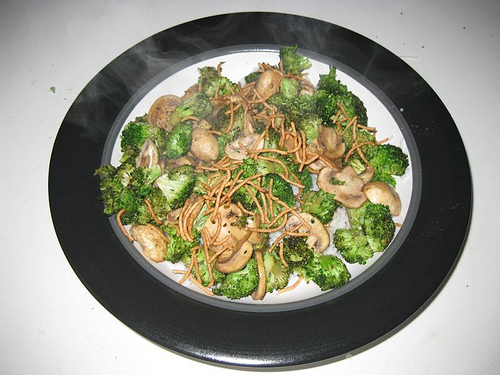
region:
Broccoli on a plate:
[97, 46, 409, 299]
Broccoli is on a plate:
[92, 44, 410, 307]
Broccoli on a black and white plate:
[93, 39, 411, 306]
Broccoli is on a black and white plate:
[92, 42, 412, 308]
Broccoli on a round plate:
[92, 40, 413, 305]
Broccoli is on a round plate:
[92, 40, 413, 309]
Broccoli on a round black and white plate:
[87, 34, 407, 309]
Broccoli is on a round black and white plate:
[89, 40, 414, 306]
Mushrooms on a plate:
[82, 40, 417, 302]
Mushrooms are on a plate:
[82, 45, 409, 296]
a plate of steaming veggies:
[113, 53, 400, 295]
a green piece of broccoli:
[311, 256, 347, 288]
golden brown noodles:
[181, 248, 216, 290]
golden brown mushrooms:
[287, 215, 330, 245]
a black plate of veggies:
[47, 8, 476, 366]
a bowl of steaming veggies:
[41, 9, 473, 363]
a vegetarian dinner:
[45, 14, 468, 353]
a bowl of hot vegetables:
[46, 4, 471, 357]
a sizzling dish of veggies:
[123, 74, 389, 281]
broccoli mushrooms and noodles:
[108, 46, 412, 304]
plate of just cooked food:
[16, 6, 489, 371]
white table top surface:
[421, 317, 496, 364]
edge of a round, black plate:
[40, 117, 90, 287]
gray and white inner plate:
[265, 291, 325, 311]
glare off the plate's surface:
[175, 330, 300, 370]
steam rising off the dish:
[115, 35, 180, 81]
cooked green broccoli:
[305, 255, 345, 285]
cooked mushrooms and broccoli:
[316, 162, 396, 252]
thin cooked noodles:
[200, 155, 235, 205]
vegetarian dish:
[95, 22, 432, 319]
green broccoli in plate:
[136, 79, 409, 306]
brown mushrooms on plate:
[115, 102, 405, 267]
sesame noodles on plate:
[131, 84, 343, 261]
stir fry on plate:
[140, 71, 380, 291]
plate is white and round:
[122, 88, 378, 290]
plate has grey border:
[137, 74, 368, 289]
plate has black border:
[4, 49, 495, 299]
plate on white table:
[77, 34, 427, 343]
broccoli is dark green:
[135, 93, 379, 309]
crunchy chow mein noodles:
[154, 96, 329, 251]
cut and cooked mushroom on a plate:
[363, 175, 408, 216]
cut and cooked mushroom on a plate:
[284, 208, 333, 250]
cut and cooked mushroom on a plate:
[316, 160, 368, 207]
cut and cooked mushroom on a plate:
[129, 220, 166, 262]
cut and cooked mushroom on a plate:
[209, 238, 254, 273]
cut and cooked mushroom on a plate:
[247, 245, 267, 303]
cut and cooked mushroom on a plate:
[187, 123, 219, 163]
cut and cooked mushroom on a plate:
[223, 131, 265, 162]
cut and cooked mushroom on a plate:
[250, 65, 280, 102]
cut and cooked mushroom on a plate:
[147, 93, 185, 129]